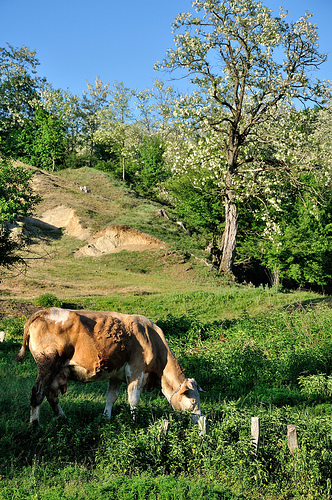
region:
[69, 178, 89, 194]
white object on top of hill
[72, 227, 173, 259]
deep hole on hill side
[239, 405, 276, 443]
short tan post in field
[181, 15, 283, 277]
large tree with white buds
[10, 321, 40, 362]
cow's tan and brown tail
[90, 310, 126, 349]
wavy bumps on side of cow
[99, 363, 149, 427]
cow's tan and brown leg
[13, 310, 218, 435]
brown and tan cow grazing in field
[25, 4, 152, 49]
clear blue skies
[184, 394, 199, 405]
tan eye on cow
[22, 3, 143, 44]
blue, clear sky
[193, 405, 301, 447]
wooden posts stuck into the ground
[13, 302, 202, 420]
brown and white cow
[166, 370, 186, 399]
cord or rope around cow's neck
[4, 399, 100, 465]
shadow on grass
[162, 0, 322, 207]
white buds on trees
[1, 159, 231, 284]
low hill behind brown and white cow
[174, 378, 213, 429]
cow's face in the grass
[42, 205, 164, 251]
bare brown areas of hill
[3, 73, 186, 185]
trees on distant hill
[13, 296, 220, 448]
Brown and white cow.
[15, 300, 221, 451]
A cow eating grass.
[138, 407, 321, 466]
An old wooden fence.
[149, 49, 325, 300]
Tall green trees in the background.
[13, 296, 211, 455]
A skinny brown cow.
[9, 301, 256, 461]
Cow outside of fence line.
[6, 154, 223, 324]
Erosion of the hillside.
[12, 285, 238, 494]
Cow with collar a on.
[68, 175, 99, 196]
Rocks are on the hillside.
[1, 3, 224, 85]
No clouds in the sky.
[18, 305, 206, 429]
Brown and white cow grazing on grass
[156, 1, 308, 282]
Tall tree with lots of leaves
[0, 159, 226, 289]
A sandy hill in the background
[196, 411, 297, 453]
broken pieces of old fence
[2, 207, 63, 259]
Shadows of the tress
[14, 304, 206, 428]
A bovine with its head down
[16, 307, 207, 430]
A large cow eating grass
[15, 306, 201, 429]
A brown and white cow eating grass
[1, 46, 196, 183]
Tall tress in the background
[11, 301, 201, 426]
A cow with its head down grazing in the grass